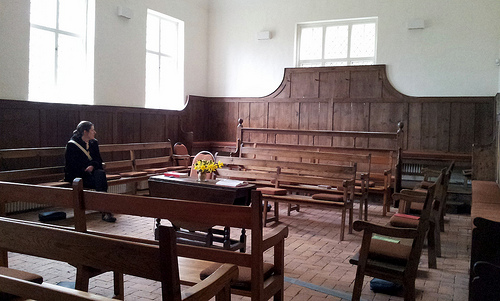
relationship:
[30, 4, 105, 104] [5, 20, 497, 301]
window in photo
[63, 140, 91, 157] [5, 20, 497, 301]
strap in photo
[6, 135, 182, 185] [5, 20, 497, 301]
bench in photo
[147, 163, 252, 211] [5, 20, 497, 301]
table in photo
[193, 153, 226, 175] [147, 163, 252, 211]
flowers on table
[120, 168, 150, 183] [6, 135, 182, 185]
cushion on bench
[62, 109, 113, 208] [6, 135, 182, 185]
woman on bench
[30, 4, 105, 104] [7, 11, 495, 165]
window in room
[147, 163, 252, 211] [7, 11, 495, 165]
table in room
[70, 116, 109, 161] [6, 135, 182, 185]
person on bench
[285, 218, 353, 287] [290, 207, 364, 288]
tiles on floor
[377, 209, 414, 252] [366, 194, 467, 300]
books on chairs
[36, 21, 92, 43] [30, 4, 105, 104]
lines on window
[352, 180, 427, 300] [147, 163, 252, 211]
chair at table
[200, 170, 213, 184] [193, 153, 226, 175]
vase has flowers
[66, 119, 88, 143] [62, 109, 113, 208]
hair on woman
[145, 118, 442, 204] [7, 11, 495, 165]
benches in room